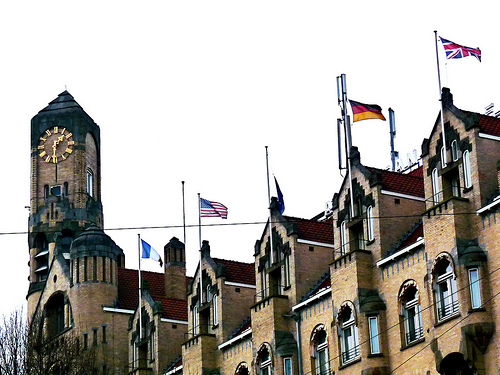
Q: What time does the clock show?
A: 1:30.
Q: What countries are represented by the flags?
A: United Kingdom, Germany, USA and France.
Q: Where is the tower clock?
A: On the left.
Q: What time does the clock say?
A: 1:30.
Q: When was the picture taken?
A: During the daytime.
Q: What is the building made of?
A: Bricks and wood with windows.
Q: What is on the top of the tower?
A: A large clock.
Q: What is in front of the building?
A: A large leafless tree.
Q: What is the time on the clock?
A: One thirty is the time on the clock.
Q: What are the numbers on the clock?
A: They are roman numbers.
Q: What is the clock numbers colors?
A: They are gold numbers.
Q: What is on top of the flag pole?
A: The British flag.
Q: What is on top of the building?
A: Flagpoles.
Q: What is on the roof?
A: Wooden slates.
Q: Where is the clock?
A: On the tower.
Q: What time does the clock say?
A: 1:30.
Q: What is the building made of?
A: Brick.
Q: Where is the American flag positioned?
A: Second flag from the left.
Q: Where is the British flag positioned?
A: On the far right.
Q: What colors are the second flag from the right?
A: Black, red, and gold.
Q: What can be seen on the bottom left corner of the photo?
A: The top of a tree.